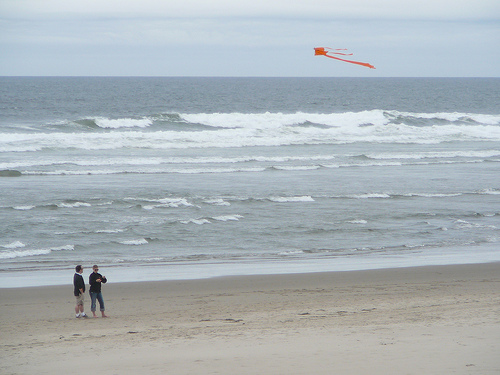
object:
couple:
[73, 265, 109, 319]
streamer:
[324, 47, 347, 50]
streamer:
[325, 51, 353, 56]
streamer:
[324, 54, 376, 69]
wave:
[0, 109, 500, 271]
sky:
[0, 0, 498, 80]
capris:
[89, 291, 105, 312]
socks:
[76, 312, 80, 316]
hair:
[93, 265, 99, 271]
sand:
[0, 260, 500, 372]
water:
[0, 76, 500, 284]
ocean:
[2, 76, 499, 270]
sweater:
[89, 271, 107, 293]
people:
[89, 265, 110, 318]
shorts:
[74, 293, 84, 306]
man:
[74, 265, 89, 320]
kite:
[313, 47, 376, 69]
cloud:
[3, 0, 499, 45]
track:
[362, 307, 376, 311]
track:
[298, 312, 311, 315]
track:
[226, 318, 243, 322]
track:
[198, 319, 210, 322]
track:
[128, 331, 136, 333]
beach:
[2, 258, 497, 373]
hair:
[75, 265, 82, 273]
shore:
[0, 244, 500, 373]